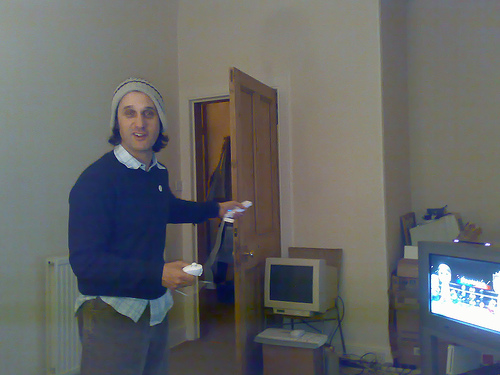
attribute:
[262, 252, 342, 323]
monitor — off, tan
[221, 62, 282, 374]
door — open, wooden, ajar, brown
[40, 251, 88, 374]
radiator — white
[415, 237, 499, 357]
television — on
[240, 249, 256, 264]
doorknob — brass-colored, brass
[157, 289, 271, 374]
carpeting — brown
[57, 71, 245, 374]
man — caucasian, looking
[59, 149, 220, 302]
shirt — long-sleeved, blue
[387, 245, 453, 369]
boxes — stacked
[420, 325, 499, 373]
tv stand — grey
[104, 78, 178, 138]
hat — beige, tan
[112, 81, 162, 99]
stripe — black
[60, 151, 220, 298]
sweater — blue, dark blue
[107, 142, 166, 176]
shirt collar — white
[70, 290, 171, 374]
pants — brown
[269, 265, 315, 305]
screen — black